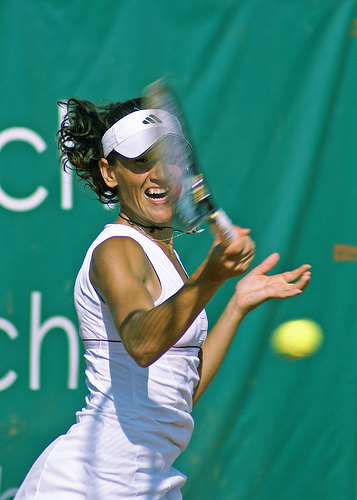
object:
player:
[138, 77, 340, 367]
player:
[4, 102, 230, 499]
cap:
[98, 107, 197, 167]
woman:
[141, 79, 259, 273]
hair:
[45, 96, 185, 204]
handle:
[196, 202, 254, 255]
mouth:
[138, 180, 181, 209]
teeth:
[137, 185, 176, 203]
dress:
[13, 221, 207, 496]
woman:
[30, 83, 357, 493]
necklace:
[112, 214, 217, 246]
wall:
[190, 30, 334, 137]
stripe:
[78, 326, 218, 362]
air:
[257, 311, 347, 360]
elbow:
[116, 321, 173, 369]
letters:
[0, 284, 82, 395]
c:
[0, 124, 50, 213]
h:
[18, 280, 86, 401]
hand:
[202, 221, 262, 273]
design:
[141, 108, 165, 129]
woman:
[119, 194, 206, 241]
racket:
[128, 63, 291, 302]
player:
[86, 119, 207, 227]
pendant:
[118, 199, 253, 236]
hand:
[229, 249, 319, 305]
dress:
[72, 335, 217, 353]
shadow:
[114, 307, 195, 370]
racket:
[109, 303, 210, 354]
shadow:
[81, 349, 173, 498]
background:
[182, 3, 324, 89]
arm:
[89, 245, 217, 368]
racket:
[142, 74, 238, 246]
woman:
[12, 96, 313, 495]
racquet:
[144, 73, 238, 248]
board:
[1, 2, 345, 498]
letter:
[0, 315, 17, 393]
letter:
[29, 288, 78, 389]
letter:
[1, 126, 47, 213]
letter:
[57, 98, 115, 210]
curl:
[67, 113, 93, 138]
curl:
[97, 190, 119, 199]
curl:
[62, 96, 86, 112]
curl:
[58, 140, 75, 148]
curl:
[59, 114, 75, 125]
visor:
[102, 109, 194, 160]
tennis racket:
[143, 75, 239, 247]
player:
[11, 94, 312, 498]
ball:
[270, 317, 323, 358]